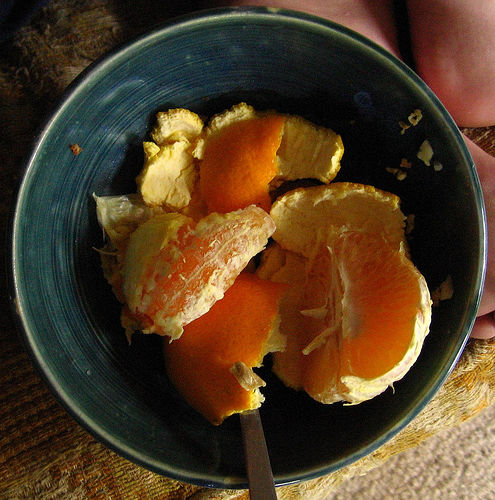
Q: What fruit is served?
A: Orange.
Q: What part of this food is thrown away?
A: Peel.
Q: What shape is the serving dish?
A: Round.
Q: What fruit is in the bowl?
A: Orange.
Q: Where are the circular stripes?
A: Inside bowl.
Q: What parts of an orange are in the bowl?
A: All parts.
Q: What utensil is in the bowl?
A: Spoon.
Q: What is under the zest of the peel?
A: White skin.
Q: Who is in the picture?
A: Person with bare feet.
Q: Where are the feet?
A: Next to bowl.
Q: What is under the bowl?
A: Yellow and white mat.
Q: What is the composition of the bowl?
A: Ceramic.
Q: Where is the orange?
A: In the bowl.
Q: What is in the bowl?
A: Orange peels.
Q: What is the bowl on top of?
A: Fabric.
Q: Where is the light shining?
A: Oranges and bowl.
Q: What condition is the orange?
A: Peeled.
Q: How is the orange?
A: Peeled.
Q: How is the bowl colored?
A: Blue.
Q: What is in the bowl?
A: Orange.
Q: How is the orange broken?
A: Segmented.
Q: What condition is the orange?
A: Peeled.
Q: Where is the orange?
A: In the bowl.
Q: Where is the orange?
A: In the bowl.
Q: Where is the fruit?
A: In the bowl.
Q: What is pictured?
A: Fruit.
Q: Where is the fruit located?
A: In a bowl.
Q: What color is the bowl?
A: Blue.